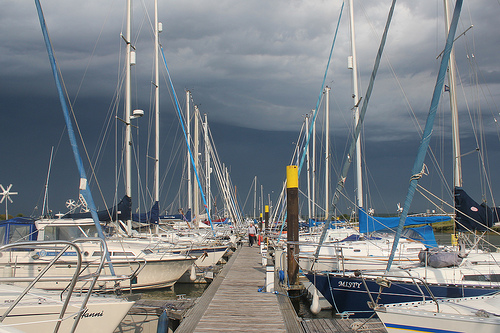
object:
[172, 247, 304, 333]
pier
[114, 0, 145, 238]
mast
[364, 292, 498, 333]
sailboat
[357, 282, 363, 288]
letter y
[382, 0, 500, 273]
sail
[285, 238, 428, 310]
boat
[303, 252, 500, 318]
boat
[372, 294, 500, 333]
boat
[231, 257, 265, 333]
ground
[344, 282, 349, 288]
letter i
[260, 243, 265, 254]
post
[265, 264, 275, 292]
post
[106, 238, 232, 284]
boats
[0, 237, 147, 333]
boat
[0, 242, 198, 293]
boats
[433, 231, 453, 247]
water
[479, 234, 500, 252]
water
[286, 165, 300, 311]
post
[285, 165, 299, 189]
yellow top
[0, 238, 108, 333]
hand rail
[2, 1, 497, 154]
sky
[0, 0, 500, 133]
cloud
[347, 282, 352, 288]
letter s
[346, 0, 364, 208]
pole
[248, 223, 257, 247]
person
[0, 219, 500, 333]
marina